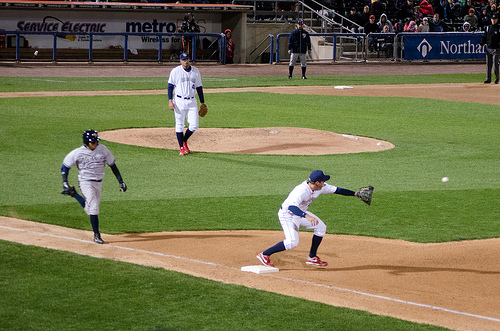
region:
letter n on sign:
[439, 39, 451, 59]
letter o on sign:
[451, 42, 458, 56]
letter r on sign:
[456, 41, 463, 56]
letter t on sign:
[463, 41, 468, 56]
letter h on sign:
[468, 37, 475, 55]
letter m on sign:
[121, 21, 143, 35]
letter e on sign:
[141, 19, 153, 35]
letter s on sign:
[13, 18, 26, 34]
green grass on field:
[102, 273, 150, 305]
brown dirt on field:
[200, 230, 234, 264]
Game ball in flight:
[437, 173, 451, 185]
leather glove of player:
[356, 179, 373, 204]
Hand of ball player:
[305, 213, 322, 227]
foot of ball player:
[255, 249, 272, 263]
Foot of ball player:
[304, 253, 326, 268]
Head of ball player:
[79, 122, 101, 152]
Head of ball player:
[177, 51, 196, 68]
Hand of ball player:
[168, 99, 180, 111]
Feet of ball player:
[171, 141, 196, 158]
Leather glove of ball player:
[196, 101, 206, 113]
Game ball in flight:
[436, 173, 456, 188]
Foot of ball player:
[254, 248, 276, 264]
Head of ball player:
[306, 168, 330, 189]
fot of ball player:
[88, 230, 111, 247]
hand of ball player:
[116, 181, 133, 195]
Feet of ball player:
[171, 143, 192, 153]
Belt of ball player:
[173, 91, 199, 101]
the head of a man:
[73, 123, 110, 163]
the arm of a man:
[179, 51, 214, 116]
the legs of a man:
[66, 156, 126, 256]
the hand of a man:
[96, 174, 133, 194]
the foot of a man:
[244, 243, 296, 280]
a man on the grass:
[148, 37, 268, 174]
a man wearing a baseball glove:
[264, 137, 404, 274]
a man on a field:
[59, 105, 159, 245]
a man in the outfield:
[146, 34, 228, 168]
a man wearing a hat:
[301, 160, 342, 202]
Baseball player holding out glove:
[256, 170, 377, 271]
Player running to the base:
[60, 128, 127, 245]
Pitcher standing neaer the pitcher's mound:
[165, 49, 208, 157]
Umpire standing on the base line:
[481, 11, 498, 89]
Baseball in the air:
[439, 171, 448, 187]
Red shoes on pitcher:
[174, 136, 192, 160]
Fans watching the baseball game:
[337, 0, 498, 38]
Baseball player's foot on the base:
[242, 248, 280, 278]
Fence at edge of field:
[0, 23, 498, 68]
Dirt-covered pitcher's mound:
[96, 124, 392, 161]